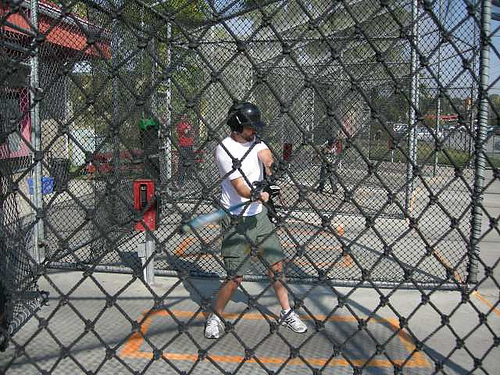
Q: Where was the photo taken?
A: It was taken at the pavement.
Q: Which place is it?
A: It is a pavement.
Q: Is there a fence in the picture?
A: Yes, there is a fence.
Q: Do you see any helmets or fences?
A: Yes, there is a fence.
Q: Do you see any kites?
A: No, there are no kites.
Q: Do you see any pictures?
A: No, there are no pictures.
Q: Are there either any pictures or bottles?
A: No, there are no pictures or bottles.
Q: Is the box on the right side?
A: No, the box is on the left of the image.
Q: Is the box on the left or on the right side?
A: The box is on the left of the image.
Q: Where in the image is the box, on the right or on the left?
A: The box is on the left of the image.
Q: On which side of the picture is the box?
A: The box is on the left of the image.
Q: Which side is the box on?
A: The box is on the left of the image.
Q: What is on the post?
A: The box is on the post.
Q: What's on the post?
A: The box is on the post.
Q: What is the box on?
A: The box is on the post.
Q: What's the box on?
A: The box is on the post.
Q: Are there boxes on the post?
A: Yes, there is a box on the post.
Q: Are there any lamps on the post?
A: No, there is a box on the post.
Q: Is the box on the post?
A: Yes, the box is on the post.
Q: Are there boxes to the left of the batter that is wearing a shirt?
A: Yes, there is a box to the left of the batter.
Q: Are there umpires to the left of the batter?
A: No, there is a box to the left of the batter.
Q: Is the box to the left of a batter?
A: Yes, the box is to the left of a batter.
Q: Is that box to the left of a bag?
A: No, the box is to the left of a batter.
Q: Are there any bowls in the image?
A: No, there are no bowls.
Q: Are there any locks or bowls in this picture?
A: No, there are no bowls or locks.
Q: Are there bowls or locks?
A: No, there are no bowls or locks.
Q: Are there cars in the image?
A: No, there are no cars.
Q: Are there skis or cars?
A: No, there are no cars or skis.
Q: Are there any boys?
A: No, there are no boys.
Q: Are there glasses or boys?
A: No, there are no boys or glasses.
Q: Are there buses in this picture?
A: No, there are no buses.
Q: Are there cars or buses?
A: No, there are no buses or cars.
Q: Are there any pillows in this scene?
A: No, there are no pillows.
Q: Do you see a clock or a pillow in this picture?
A: No, there are no pillows or clocks.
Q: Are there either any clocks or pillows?
A: No, there are no pillows or clocks.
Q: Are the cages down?
A: Yes, the cages are down.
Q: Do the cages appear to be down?
A: Yes, the cages are down.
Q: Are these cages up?
A: No, the cages are down.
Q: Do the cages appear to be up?
A: No, the cages are down.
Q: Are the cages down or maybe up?
A: The cages are down.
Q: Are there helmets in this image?
A: Yes, there is a helmet.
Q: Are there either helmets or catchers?
A: Yes, there is a helmet.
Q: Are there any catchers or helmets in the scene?
A: Yes, there is a helmet.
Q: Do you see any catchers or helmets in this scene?
A: Yes, there is a helmet.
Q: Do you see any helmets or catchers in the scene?
A: Yes, there is a helmet.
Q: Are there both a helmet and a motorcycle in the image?
A: No, there is a helmet but no motorcycles.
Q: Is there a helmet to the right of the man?
A: Yes, there is a helmet to the right of the man.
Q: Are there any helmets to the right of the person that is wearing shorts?
A: Yes, there is a helmet to the right of the man.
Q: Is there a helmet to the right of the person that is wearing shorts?
A: Yes, there is a helmet to the right of the man.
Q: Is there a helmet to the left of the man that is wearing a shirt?
A: No, the helmet is to the right of the man.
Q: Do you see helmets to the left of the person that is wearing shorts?
A: No, the helmet is to the right of the man.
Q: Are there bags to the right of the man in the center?
A: No, there is a helmet to the right of the man.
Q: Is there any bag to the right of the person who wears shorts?
A: No, there is a helmet to the right of the man.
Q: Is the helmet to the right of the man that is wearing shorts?
A: Yes, the helmet is to the right of the man.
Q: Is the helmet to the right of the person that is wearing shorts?
A: Yes, the helmet is to the right of the man.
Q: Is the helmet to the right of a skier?
A: No, the helmet is to the right of the man.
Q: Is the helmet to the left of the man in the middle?
A: No, the helmet is to the right of the man.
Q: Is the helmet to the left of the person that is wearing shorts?
A: No, the helmet is to the right of the man.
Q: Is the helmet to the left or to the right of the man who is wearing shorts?
A: The helmet is to the right of the man.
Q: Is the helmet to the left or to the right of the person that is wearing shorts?
A: The helmet is to the right of the man.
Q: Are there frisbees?
A: No, there are no frisbees.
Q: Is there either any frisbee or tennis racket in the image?
A: No, there are no frisbees or rackets.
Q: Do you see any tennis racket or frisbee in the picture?
A: No, there are no frisbees or rackets.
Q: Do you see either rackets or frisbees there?
A: No, there are no frisbees or rackets.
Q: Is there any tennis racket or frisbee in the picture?
A: No, there are no frisbees or rackets.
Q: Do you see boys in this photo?
A: No, there are no boys.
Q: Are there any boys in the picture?
A: No, there are no boys.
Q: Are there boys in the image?
A: No, there are no boys.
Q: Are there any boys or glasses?
A: No, there are no boys or glasses.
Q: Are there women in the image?
A: No, there are no women.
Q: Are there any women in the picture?
A: No, there are no women.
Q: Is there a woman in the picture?
A: No, there are no women.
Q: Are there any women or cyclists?
A: No, there are no women or cyclists.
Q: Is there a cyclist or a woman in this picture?
A: No, there are no women or cyclists.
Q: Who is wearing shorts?
A: The man is wearing shorts.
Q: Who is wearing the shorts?
A: The man is wearing shorts.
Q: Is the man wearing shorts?
A: Yes, the man is wearing shorts.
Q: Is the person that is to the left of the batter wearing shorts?
A: Yes, the man is wearing shorts.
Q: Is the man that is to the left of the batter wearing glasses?
A: No, the man is wearing shorts.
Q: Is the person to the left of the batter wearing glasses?
A: No, the man is wearing shorts.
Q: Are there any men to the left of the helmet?
A: Yes, there is a man to the left of the helmet.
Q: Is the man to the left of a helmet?
A: Yes, the man is to the left of a helmet.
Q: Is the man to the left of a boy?
A: No, the man is to the left of a helmet.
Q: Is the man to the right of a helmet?
A: No, the man is to the left of a helmet.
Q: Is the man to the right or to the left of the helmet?
A: The man is to the left of the helmet.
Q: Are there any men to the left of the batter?
A: Yes, there is a man to the left of the batter.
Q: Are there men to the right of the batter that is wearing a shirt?
A: No, the man is to the left of the batter.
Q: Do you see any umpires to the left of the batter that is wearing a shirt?
A: No, there is a man to the left of the batter.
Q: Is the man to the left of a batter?
A: Yes, the man is to the left of a batter.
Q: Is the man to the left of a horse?
A: No, the man is to the left of a batter.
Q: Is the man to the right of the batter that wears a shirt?
A: No, the man is to the left of the batter.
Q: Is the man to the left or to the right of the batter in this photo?
A: The man is to the left of the batter.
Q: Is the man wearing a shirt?
A: Yes, the man is wearing a shirt.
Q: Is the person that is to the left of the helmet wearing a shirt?
A: Yes, the man is wearing a shirt.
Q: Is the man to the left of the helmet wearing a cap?
A: No, the man is wearing a shirt.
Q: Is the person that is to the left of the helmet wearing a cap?
A: No, the man is wearing a shirt.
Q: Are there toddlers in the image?
A: No, there are no toddlers.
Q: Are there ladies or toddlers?
A: No, there are no toddlers or ladies.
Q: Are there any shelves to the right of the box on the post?
A: No, there is a batter to the right of the box.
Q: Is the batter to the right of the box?
A: Yes, the batter is to the right of the box.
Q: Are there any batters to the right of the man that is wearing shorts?
A: Yes, there is a batter to the right of the man.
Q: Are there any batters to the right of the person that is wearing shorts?
A: Yes, there is a batter to the right of the man.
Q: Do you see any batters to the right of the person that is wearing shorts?
A: Yes, there is a batter to the right of the man.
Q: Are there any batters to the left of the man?
A: No, the batter is to the right of the man.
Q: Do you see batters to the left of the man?
A: No, the batter is to the right of the man.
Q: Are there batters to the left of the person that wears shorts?
A: No, the batter is to the right of the man.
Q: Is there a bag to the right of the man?
A: No, there is a batter to the right of the man.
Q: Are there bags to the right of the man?
A: No, there is a batter to the right of the man.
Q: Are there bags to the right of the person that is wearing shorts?
A: No, there is a batter to the right of the man.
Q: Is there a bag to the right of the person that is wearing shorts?
A: No, there is a batter to the right of the man.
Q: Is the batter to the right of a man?
A: Yes, the batter is to the right of a man.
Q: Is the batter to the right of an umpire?
A: No, the batter is to the right of a man.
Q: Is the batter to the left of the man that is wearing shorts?
A: No, the batter is to the right of the man.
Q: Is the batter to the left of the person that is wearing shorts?
A: No, the batter is to the right of the man.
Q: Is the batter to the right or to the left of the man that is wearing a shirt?
A: The batter is to the right of the man.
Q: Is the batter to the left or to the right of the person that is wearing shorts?
A: The batter is to the right of the man.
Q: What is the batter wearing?
A: The batter is wearing a shirt.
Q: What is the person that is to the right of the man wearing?
A: The batter is wearing a shirt.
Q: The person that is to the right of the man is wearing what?
A: The batter is wearing a shirt.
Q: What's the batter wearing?
A: The batter is wearing a shirt.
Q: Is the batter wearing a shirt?
A: Yes, the batter is wearing a shirt.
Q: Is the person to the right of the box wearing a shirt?
A: Yes, the batter is wearing a shirt.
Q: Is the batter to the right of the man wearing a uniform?
A: No, the batter is wearing a shirt.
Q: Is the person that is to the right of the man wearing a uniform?
A: No, the batter is wearing a shirt.